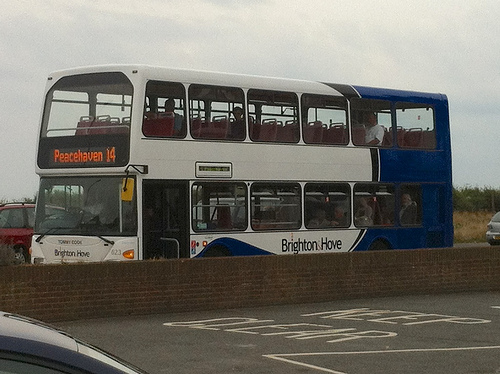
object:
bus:
[25, 63, 455, 262]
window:
[39, 73, 133, 169]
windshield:
[32, 180, 139, 238]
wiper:
[35, 224, 76, 242]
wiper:
[72, 224, 115, 245]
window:
[143, 79, 189, 141]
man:
[164, 98, 183, 135]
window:
[187, 84, 247, 145]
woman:
[228, 107, 245, 140]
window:
[247, 84, 300, 147]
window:
[301, 92, 350, 149]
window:
[348, 97, 394, 148]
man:
[362, 112, 385, 145]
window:
[395, 103, 439, 153]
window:
[400, 183, 423, 226]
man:
[395, 192, 419, 225]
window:
[354, 183, 398, 227]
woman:
[355, 195, 375, 229]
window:
[305, 182, 351, 233]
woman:
[308, 209, 328, 227]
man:
[329, 207, 348, 227]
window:
[249, 182, 304, 232]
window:
[193, 184, 249, 230]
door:
[142, 175, 192, 264]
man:
[81, 183, 117, 225]